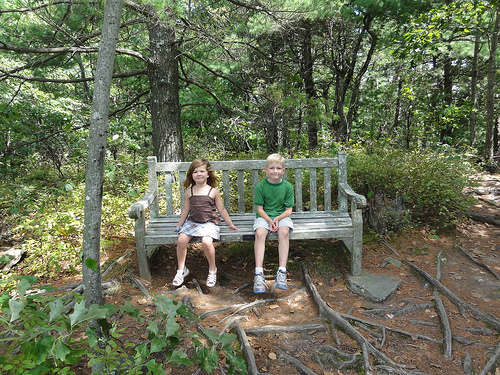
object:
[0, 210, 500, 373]
roots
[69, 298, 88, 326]
leaf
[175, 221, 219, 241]
skirt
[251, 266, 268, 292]
feet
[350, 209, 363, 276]
leg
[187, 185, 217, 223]
top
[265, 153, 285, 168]
hair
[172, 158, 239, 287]
child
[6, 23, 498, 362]
not seen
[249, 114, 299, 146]
wall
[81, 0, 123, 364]
trunk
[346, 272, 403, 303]
large rock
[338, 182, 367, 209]
arm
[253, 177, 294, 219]
t-shirt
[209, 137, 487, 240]
bushes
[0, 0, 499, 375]
forest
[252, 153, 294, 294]
boy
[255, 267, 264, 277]
sock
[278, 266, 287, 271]
sock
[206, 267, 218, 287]
sandal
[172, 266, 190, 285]
sandal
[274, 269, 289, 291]
shoe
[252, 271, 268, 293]
shoe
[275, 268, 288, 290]
foot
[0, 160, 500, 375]
ground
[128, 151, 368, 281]
bench